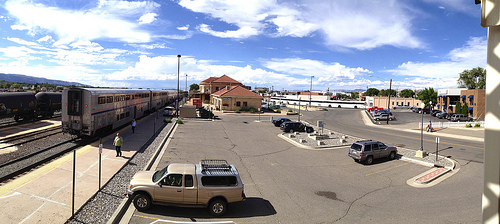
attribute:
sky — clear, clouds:
[1, 0, 485, 80]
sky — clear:
[185, 40, 318, 57]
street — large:
[130, 111, 469, 223]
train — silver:
[57, 82, 189, 139]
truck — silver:
[344, 135, 400, 166]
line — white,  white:
[145, 216, 236, 223]